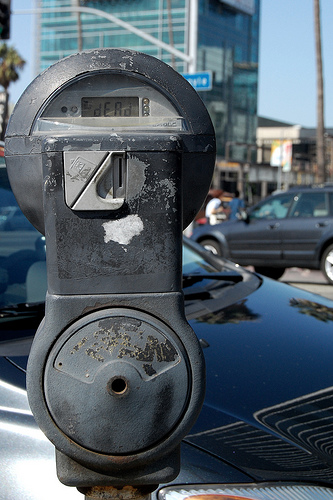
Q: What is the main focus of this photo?
A: A parking meter.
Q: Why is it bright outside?
A: It's daytime.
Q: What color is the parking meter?
A: Gray.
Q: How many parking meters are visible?
A: One.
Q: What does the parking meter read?
A: DEAd.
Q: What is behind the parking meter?
A: A car.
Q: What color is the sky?
A: Blue.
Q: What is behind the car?
A: A building.